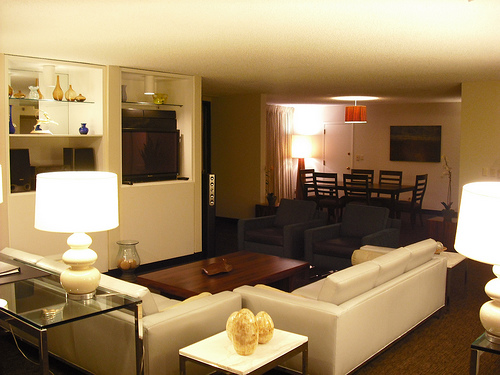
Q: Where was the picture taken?
A: Living room.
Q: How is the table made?
A: Of glass.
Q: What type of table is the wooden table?
A: Coffee table.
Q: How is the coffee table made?
A: Of wood.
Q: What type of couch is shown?
A: Fabric.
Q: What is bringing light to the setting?
A: A lamp.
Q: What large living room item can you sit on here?
A: Couch.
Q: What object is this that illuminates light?
A: Lamp.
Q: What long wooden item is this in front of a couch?
A: Table.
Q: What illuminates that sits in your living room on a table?
A: Lamp.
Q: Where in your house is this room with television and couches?
A: Living room.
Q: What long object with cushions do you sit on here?
A: Couch.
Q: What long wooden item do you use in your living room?
A: Coffee table.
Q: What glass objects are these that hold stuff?
A: Shelves.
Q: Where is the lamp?
A: On the table.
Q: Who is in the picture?
A: Nobody.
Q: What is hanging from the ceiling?
A: A light fixture.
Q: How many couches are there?
A: Two.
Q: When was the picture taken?
A: In the evening.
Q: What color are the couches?
A: White.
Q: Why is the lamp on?
A: To illuminate the room.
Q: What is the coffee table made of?
A: Wood.